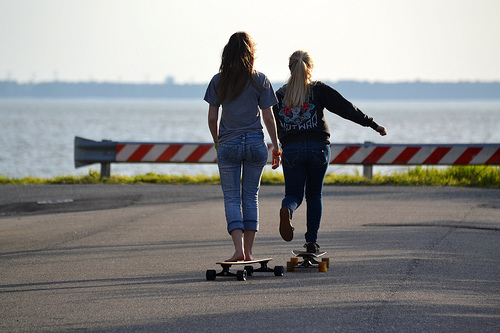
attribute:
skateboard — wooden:
[199, 247, 287, 285]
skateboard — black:
[280, 245, 337, 275]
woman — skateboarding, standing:
[200, 26, 289, 288]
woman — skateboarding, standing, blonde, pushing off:
[272, 48, 390, 277]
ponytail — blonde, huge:
[282, 49, 317, 113]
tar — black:
[2, 181, 498, 331]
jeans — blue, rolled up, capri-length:
[209, 128, 270, 239]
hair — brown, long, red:
[212, 30, 259, 109]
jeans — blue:
[273, 139, 332, 242]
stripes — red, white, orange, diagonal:
[112, 139, 499, 172]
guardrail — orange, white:
[69, 128, 500, 194]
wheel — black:
[201, 266, 220, 284]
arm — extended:
[321, 82, 390, 145]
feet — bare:
[218, 243, 259, 263]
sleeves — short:
[198, 76, 280, 111]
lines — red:
[156, 140, 180, 166]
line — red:
[124, 138, 152, 166]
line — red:
[391, 143, 422, 169]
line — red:
[452, 142, 486, 168]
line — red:
[422, 141, 451, 167]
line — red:
[182, 137, 215, 166]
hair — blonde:
[278, 46, 320, 120]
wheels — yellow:
[282, 253, 334, 279]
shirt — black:
[272, 78, 380, 151]